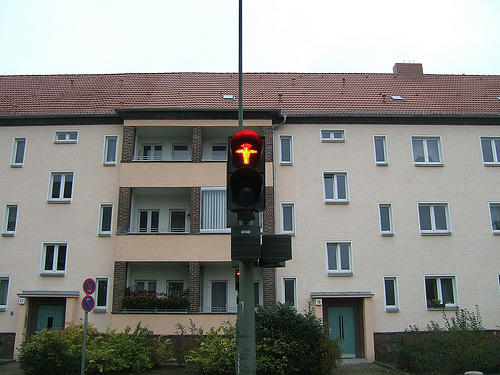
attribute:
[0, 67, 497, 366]
building — beige, closed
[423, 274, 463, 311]
window — open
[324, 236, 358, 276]
window — closed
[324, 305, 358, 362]
door — green, closed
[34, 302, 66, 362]
door — green, closed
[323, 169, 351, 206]
window — closed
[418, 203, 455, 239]
window — closed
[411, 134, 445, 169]
window — closed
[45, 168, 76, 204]
window — closed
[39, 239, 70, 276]
window — closed